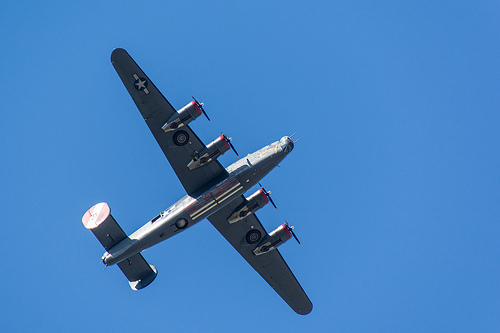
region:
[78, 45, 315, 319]
silver plane flying in the sky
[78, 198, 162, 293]
underneath of a plane's tail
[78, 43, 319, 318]
plane in the sky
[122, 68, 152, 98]
star logo design under the wing of a plane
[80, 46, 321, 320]
jet flying in the sky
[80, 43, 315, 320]
silver jet with a star logo under its wing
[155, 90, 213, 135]
propeller on a silver jet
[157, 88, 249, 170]
two propellers on a jet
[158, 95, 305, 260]
four propellers on a jet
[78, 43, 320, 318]
jet soaring in the sky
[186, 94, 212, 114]
propeller on front of plane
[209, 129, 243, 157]
propeller on front of plane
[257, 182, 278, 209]
propeller on front of plane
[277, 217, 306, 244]
propeller on front of plane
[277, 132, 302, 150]
front guns on plane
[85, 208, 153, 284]
silver tail fin of plane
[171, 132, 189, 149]
logo on bottom of plane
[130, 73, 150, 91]
white star on bottom of plane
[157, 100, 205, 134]
red and silver propeller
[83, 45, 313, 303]
A plane in the sky.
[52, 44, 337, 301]
The plane is flying in the sky.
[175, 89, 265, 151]
Propellers on the plane.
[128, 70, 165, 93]
A white star on the wing.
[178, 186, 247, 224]
Two white stripes on the plane.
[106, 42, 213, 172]
Wing of the plane.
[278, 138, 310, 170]
Front of the plane.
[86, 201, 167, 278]
Tail of the plane.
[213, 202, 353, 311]
Left wing of the plane.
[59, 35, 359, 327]
a gray fighter jet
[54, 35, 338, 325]
a gray fighter jet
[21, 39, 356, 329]
a gray fighter jet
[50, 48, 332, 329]
a gray fighter jet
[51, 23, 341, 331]
a gray fighter jet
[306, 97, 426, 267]
the blue sky is clear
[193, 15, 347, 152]
the blue sky is clear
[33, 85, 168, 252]
the blue sky is clear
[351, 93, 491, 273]
the blue sky is clear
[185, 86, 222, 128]
Black and red propeller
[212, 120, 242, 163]
Black and red propeller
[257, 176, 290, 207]
Black and red propeller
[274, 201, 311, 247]
Black and red propeller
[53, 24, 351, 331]
Grey airplane in the sky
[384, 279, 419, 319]
Part of pretty blue sky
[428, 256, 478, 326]
Part of pretty blue sky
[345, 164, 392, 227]
Part of pretty blue sky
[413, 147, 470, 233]
Part of pretty blue sky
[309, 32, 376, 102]
Part of pretty blue sky